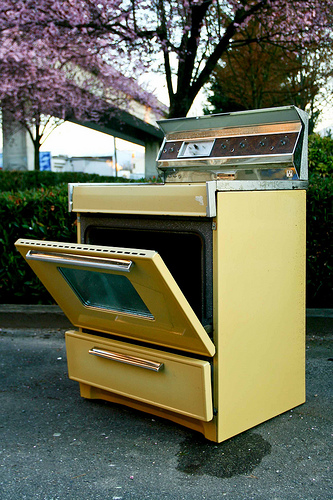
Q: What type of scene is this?
A: Outdoor.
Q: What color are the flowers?
A: Purple.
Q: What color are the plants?
A: Green.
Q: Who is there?
A: No one.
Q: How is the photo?
A: Clear.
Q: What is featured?
A: Oven.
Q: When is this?
A: Daytime.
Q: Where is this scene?
A: Outside a house.